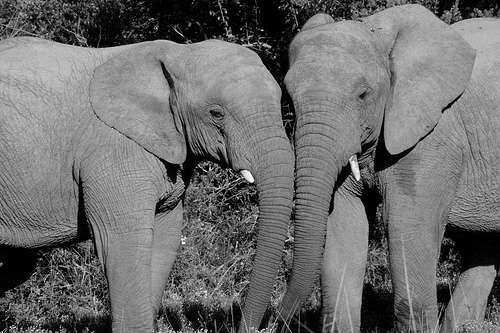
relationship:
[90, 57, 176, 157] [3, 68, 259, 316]
ear of elephant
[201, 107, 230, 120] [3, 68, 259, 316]
eye of elephant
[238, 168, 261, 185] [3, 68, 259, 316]
tusk of elephant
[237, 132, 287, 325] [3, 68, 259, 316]
trunk of elephant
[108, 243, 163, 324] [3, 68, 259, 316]
leg of elephant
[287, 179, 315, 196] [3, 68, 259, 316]
nose of elephant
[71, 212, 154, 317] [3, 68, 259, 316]
legs of elephant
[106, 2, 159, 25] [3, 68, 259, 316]
trees behind elephant